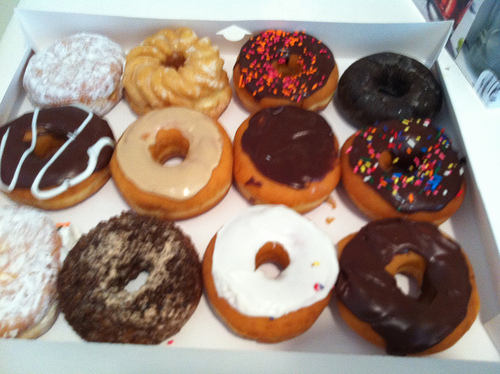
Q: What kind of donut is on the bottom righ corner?
A: Chocolate donut.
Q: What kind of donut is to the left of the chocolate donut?
A: A frosted donut.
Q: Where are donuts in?
A: A box.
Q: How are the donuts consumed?
A: By eating.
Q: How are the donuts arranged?
A: Next to each other.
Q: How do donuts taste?
A: Sweet.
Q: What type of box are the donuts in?
A: Cardboard.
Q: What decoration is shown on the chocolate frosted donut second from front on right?
A: Sprinkles.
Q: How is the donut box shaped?
A: In a square.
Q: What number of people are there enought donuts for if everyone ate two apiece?
A: Six.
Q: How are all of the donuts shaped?
A: They are all round.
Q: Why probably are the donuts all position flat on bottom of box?
A: So they will not stick together.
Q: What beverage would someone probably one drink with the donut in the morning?
A: Coffee.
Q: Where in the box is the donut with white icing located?
A: Front row second from right.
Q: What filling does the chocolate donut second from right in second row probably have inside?
A: Creme.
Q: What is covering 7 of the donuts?
A: Frosting.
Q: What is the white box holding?
A: Doughnuts.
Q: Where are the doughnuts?
A: Inside a box.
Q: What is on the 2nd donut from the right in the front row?
A: White icing.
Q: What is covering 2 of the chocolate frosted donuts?
A: Sprinkles.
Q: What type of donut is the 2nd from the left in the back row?
A: A cruller.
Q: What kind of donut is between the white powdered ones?
A: Chocolate frosted with white icing.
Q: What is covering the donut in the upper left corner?
A: Powdered sugar.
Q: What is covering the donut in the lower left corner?
A: Powdered sugar.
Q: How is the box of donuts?
A: Full.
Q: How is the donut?
A: Sweet and round.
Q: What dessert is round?
A: The donut.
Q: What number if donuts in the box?
A: A dozen.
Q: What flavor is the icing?
A: Carmel.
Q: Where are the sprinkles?
A: On the donuts.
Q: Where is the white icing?
A: On the donut.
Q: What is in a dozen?
A: The donuts.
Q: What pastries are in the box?
A: Donuts.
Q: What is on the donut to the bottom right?
A: Chocolate.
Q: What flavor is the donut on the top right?
A: Chocolate.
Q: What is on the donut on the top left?
A: Powdered sugar.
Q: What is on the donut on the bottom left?
A: Powdered sugar.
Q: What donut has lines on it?
A: The middle row far left.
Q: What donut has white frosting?
A: The donut second from the right on the bottom row.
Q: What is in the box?
A: Doughnuts.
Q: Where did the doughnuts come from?
A: The bakery.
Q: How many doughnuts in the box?
A: 12.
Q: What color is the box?
A: White.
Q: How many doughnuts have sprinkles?
A: Three.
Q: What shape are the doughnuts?
A: Round.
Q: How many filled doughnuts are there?
A: Two.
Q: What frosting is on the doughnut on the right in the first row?
A: Chocolate.